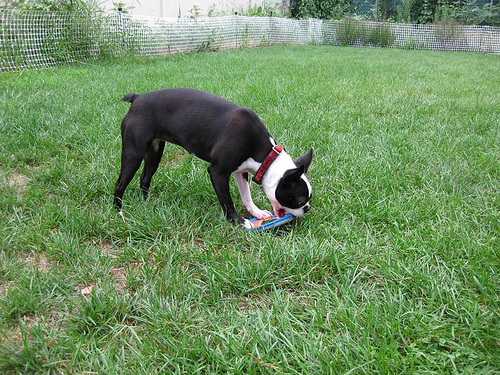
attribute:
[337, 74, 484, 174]
grass — green color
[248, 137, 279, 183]
red collar — Red 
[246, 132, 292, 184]
collar — red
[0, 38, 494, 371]
grass — long, green, yellow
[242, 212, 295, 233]
frisbee — blue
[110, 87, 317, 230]
dog — black, white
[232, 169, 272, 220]
front leg — white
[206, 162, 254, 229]
front leg — black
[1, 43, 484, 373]
yard — wire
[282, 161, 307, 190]
ear — black, erect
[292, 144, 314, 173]
ear — black, erect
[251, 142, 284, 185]
collar — red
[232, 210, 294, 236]
frisbee — blue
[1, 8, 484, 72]
chain fence — white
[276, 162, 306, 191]
ear — pointed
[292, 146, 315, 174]
ear — pointed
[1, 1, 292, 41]
wall — white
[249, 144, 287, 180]
collar — red, leather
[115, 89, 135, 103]
tail — short, stubby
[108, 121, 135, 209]
leg — black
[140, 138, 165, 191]
leg — black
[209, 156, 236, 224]
leg — black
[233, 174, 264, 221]
leg — white